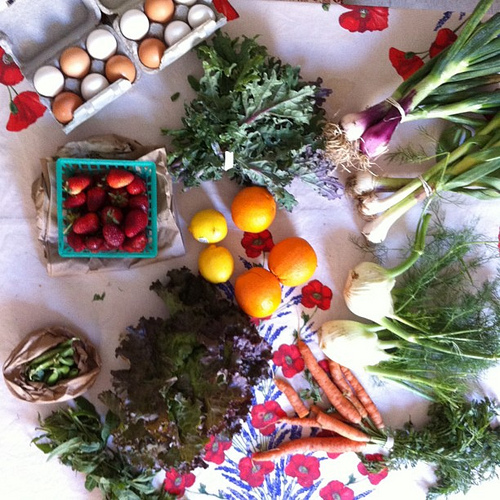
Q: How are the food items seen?
A: From above.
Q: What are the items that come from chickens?
A: Eggs.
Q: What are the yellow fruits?
A: Lemons.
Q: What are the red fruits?
A: Strawberries.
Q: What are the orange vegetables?
A: Carrots.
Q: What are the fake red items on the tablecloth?
A: Flowers.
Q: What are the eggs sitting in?
A: A carton.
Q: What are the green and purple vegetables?
A: Onions.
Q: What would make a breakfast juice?
A: Oranges.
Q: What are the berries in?
A: A green basket.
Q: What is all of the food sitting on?
A: A flower tablecloth.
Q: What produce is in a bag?
A: Peas.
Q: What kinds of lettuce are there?
A: Green and purple.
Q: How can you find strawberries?
A: Green box.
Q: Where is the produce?
A: On a tablecloth.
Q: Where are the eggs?
A: In a carton.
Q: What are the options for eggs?
A: Brown or white.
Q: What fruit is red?
A: Strawberries.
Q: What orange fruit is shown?
A: Oranges.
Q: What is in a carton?
A: Eggs.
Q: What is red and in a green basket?
A: Strawberries.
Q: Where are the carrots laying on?
A: A flowered cloth.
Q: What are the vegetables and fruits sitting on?
A: White surface.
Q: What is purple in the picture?
A: Radishes.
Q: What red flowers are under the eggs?
A: Poppies.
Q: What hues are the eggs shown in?
A: Brown and white.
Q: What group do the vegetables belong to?
A: Root group.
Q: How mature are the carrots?
A: They are small.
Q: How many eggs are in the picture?
A: 11.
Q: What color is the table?
A: Red and white.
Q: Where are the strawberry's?
A: Top left.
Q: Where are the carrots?
A: Bottom right.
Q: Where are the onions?
A: Top right.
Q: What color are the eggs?
A: Brown and white.